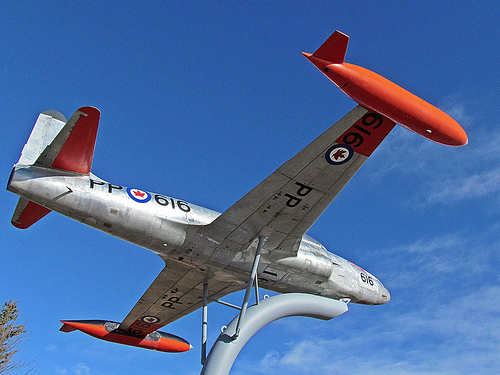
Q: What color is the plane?
A: Red and silver.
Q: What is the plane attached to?
A: Metal beam.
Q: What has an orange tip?
A: Wing.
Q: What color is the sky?
A: Blue.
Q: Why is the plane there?
A: Display.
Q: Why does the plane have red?
A: Training.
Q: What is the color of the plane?
A: Red and silver.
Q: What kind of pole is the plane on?
A: Metal.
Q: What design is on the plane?
A: Maple leaf.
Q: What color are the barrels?
A: Red.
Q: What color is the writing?
A: Black.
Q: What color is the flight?
A: Orange and white.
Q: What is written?
A: Numbers.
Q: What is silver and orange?
A: The plane.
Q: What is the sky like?
A: Blue.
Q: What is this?
A: A statue.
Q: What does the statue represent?
A: An airplane.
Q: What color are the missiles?
A: Red.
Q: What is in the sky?
A: Clouds.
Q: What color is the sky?
A: Blue.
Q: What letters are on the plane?
A: PP.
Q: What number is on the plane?
A: 616.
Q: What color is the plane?
A: Silver.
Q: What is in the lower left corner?
A: A tree.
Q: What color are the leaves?
A: Green.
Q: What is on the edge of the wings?
A: Torpedos.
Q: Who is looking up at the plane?
A: The photographer.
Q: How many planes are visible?
A: One.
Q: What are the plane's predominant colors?
A: Silver and red.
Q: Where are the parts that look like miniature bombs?
A: At the wingtips.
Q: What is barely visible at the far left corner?
A: The branches of a tree.